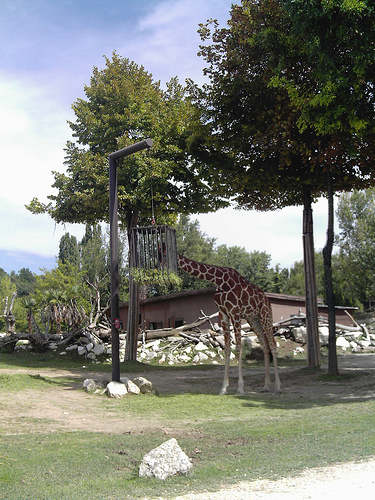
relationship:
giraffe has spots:
[153, 244, 283, 387] [240, 293, 249, 305]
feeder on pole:
[125, 234, 171, 271] [109, 165, 119, 386]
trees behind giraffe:
[146, 89, 291, 137] [153, 244, 283, 387]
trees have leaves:
[146, 89, 291, 137] [297, 40, 308, 49]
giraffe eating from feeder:
[153, 244, 283, 387] [125, 234, 171, 271]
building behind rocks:
[179, 300, 198, 319] [106, 382, 139, 398]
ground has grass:
[84, 412, 122, 472] [98, 451, 104, 458]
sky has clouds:
[91, 8, 116, 24] [29, 87, 48, 98]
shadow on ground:
[183, 383, 189, 389] [84, 412, 122, 472]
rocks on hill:
[106, 382, 139, 398] [54, 316, 67, 327]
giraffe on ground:
[153, 244, 283, 387] [84, 412, 122, 472]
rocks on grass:
[106, 382, 139, 398] [98, 451, 104, 458]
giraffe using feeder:
[153, 244, 283, 387] [125, 234, 171, 271]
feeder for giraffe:
[125, 234, 171, 271] [153, 244, 283, 387]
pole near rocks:
[109, 165, 119, 386] [106, 382, 139, 398]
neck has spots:
[189, 263, 213, 273] [240, 293, 249, 305]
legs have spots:
[233, 317, 241, 336] [240, 293, 249, 305]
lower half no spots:
[237, 361, 242, 385] [240, 293, 249, 305]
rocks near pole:
[106, 382, 139, 398] [109, 165, 119, 386]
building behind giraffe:
[179, 300, 198, 319] [153, 244, 283, 387]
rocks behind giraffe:
[106, 382, 139, 398] [153, 244, 283, 387]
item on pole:
[114, 320, 122, 328] [109, 165, 119, 386]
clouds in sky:
[29, 87, 48, 98] [91, 8, 116, 24]